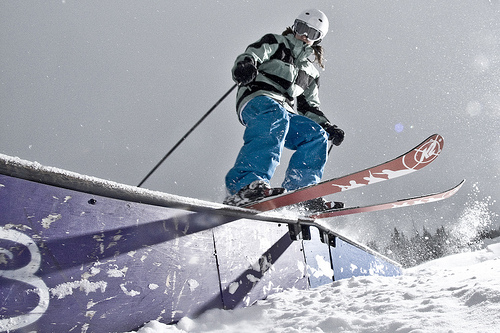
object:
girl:
[137, 7, 345, 213]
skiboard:
[303, 178, 466, 218]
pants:
[224, 95, 329, 196]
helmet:
[293, 9, 329, 41]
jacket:
[231, 33, 329, 126]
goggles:
[290, 18, 324, 43]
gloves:
[320, 124, 346, 146]